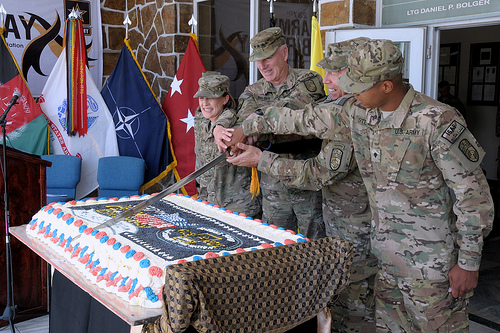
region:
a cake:
[32, 141, 301, 306]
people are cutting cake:
[160, 18, 495, 244]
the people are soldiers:
[143, 10, 489, 295]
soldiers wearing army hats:
[161, 20, 415, 167]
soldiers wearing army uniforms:
[148, 93, 488, 218]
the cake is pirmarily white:
[26, 174, 280, 326]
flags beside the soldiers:
[44, 11, 231, 189]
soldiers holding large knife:
[184, 19, 437, 190]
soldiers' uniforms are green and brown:
[163, 22, 489, 297]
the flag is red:
[162, 27, 241, 188]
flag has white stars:
[158, 69, 218, 160]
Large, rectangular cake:
[2, 177, 367, 304]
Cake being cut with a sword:
[15, 135, 338, 287]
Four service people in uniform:
[173, 25, 496, 329]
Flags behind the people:
[0, 6, 345, 210]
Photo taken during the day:
[3, 4, 495, 327]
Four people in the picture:
[185, 27, 486, 328]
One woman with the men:
[175, 55, 267, 240]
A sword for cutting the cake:
[95, 122, 270, 239]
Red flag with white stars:
[157, 32, 249, 202]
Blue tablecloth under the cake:
[25, 265, 145, 330]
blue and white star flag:
[95, 8, 177, 188]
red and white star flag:
[157, 12, 214, 199]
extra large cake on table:
[26, 186, 315, 318]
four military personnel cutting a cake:
[179, 18, 496, 330]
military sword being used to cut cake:
[80, 127, 258, 228]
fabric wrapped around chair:
[155, 235, 361, 332]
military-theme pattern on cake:
[68, 191, 278, 272]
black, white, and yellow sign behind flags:
[0, 0, 102, 117]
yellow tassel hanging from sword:
[243, 161, 264, 201]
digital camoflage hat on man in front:
[336, 36, 407, 97]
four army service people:
[157, 17, 459, 205]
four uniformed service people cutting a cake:
[31, 20, 483, 295]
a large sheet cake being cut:
[14, 176, 332, 318]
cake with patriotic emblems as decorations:
[63, 195, 273, 271]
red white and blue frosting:
[16, 193, 168, 303]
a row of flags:
[2, 11, 237, 191]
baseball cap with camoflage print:
[330, 35, 412, 110]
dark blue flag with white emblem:
[90, 29, 192, 198]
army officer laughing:
[222, 20, 309, 147]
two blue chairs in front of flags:
[14, 91, 149, 226]